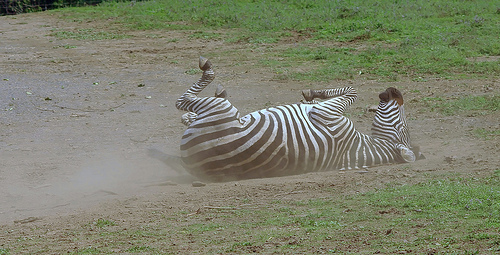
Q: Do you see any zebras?
A: Yes, there is a zebra.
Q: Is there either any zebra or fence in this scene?
A: Yes, there is a zebra.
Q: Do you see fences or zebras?
A: Yes, there is a zebra.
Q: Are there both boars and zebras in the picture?
A: No, there is a zebra but no boars.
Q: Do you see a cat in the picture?
A: No, there are no cats.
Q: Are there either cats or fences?
A: No, there are no cats or fences.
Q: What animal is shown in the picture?
A: The animal is a zebra.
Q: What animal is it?
A: The animal is a zebra.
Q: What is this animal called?
A: This is a zebra.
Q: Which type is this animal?
A: This is a zebra.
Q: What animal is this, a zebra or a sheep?
A: This is a zebra.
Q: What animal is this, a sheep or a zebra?
A: This is a zebra.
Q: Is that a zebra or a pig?
A: That is a zebra.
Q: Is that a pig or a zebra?
A: That is a zebra.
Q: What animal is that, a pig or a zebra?
A: That is a zebra.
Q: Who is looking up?
A: The zebra is looking up.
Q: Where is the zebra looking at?
A: The zebra is looking up.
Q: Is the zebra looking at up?
A: Yes, the zebra is looking up.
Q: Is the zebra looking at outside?
A: No, the zebra is looking up.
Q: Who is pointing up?
A: The zebra is pointing up.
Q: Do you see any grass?
A: Yes, there is grass.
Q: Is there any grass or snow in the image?
A: Yes, there is grass.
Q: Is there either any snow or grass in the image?
A: Yes, there is grass.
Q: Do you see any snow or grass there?
A: Yes, there is grass.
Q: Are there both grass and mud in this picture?
A: No, there is grass but no mud.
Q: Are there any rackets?
A: No, there are no rackets.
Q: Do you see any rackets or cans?
A: No, there are no rackets or cans.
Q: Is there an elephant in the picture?
A: No, there are no elephants.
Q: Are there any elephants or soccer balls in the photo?
A: No, there are no elephants or soccer balls.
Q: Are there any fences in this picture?
A: No, there are no fences.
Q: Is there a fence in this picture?
A: No, there are no fences.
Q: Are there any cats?
A: No, there are no cats.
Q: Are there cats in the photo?
A: No, there are no cats.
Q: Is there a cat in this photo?
A: No, there are no cats.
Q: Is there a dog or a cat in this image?
A: No, there are no cats or dogs.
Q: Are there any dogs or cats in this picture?
A: No, there are no cats or dogs.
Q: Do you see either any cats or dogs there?
A: No, there are no cats or dogs.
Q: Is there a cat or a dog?
A: No, there are no cats or dogs.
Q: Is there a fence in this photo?
A: No, there are no fences.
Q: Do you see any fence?
A: No, there are no fences.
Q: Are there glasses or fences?
A: No, there are no fences or glasses.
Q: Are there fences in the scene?
A: No, there are no fences.